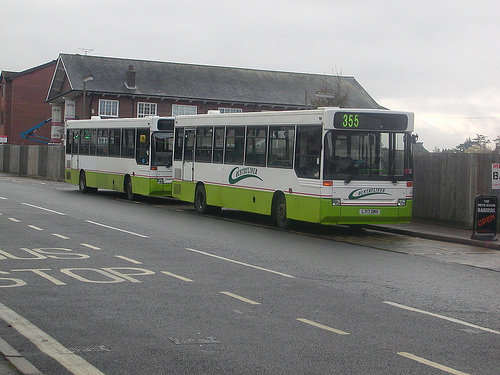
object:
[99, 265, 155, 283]
word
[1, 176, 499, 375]
street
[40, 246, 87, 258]
word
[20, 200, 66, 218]
line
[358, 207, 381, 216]
license plate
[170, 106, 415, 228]
bus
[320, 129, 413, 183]
windshield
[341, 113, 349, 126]
number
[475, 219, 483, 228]
word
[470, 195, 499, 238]
sign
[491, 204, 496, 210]
word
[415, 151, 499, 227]
fence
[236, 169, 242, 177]
writing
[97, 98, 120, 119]
window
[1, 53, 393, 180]
building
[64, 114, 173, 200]
bus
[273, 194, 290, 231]
right wheel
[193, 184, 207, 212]
right tire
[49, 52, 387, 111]
roof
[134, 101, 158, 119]
window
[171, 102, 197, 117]
window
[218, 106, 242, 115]
window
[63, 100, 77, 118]
window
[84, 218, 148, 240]
line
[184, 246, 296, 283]
line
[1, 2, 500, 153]
sky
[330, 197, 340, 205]
light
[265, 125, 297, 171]
window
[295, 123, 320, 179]
window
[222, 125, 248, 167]
window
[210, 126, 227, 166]
window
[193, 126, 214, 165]
window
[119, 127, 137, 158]
window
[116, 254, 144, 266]
line